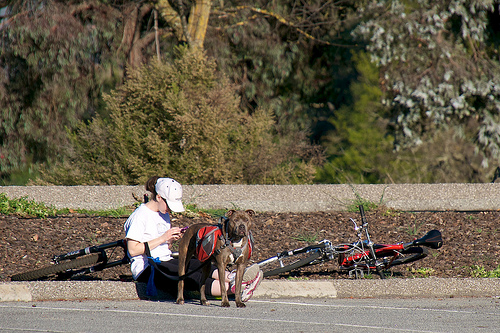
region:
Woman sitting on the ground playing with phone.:
[128, 175, 262, 302]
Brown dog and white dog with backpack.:
[176, 209, 252, 307]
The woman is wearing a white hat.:
[154, 176, 185, 212]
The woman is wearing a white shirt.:
[122, 203, 174, 274]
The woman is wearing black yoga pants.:
[136, 256, 213, 299]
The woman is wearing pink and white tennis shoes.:
[230, 262, 263, 303]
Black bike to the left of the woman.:
[11, 239, 128, 280]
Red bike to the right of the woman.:
[256, 202, 442, 276]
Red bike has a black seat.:
[413, 228, 440, 247]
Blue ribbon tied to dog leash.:
[146, 255, 161, 299]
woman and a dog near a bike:
[135, 170, 462, 312]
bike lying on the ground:
[281, 214, 496, 284]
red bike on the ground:
[281, 205, 486, 299]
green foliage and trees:
[45, 15, 477, 122]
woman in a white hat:
[136, 172, 193, 292]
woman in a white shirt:
[127, 179, 187, 284]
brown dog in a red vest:
[194, 200, 269, 272]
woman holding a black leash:
[138, 233, 272, 283]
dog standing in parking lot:
[178, 215, 363, 332]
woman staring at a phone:
[136, 167, 208, 277]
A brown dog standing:
[171, 210, 249, 307]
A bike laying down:
[261, 205, 435, 281]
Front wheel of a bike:
[12, 254, 107, 281]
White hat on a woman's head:
[151, 175, 189, 215]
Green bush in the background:
[63, 48, 247, 182]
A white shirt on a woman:
[126, 202, 178, 281]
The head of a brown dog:
[225, 205, 255, 236]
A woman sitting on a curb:
[124, 179, 266, 300]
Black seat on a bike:
[411, 224, 444, 253]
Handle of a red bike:
[348, 203, 386, 278]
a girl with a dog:
[122, 175, 257, 306]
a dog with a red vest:
[174, 203, 257, 304]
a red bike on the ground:
[268, 205, 452, 276]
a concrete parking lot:
[53, 300, 473, 323]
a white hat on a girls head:
[153, 170, 184, 218]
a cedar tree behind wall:
[77, 45, 242, 187]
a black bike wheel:
[19, 244, 111, 283]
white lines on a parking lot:
[234, 295, 386, 323]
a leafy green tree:
[326, 55, 386, 179]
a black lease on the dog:
[140, 246, 220, 280]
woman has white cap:
[110, 170, 190, 267]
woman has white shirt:
[133, 190, 179, 266]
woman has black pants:
[150, 256, 190, 292]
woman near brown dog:
[172, 199, 276, 317]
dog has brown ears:
[220, 201, 262, 213]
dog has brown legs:
[165, 257, 268, 313]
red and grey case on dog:
[177, 219, 242, 267]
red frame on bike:
[265, 195, 405, 267]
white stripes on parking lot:
[37, 289, 388, 331]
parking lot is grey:
[290, 292, 463, 331]